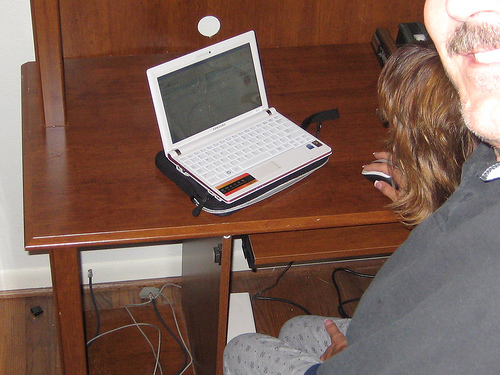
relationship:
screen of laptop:
[172, 42, 261, 136] [145, 29, 333, 205]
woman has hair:
[219, 44, 479, 375] [380, 91, 452, 188]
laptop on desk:
[145, 29, 333, 205] [20, 43, 455, 375]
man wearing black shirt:
[311, 0, 500, 375] [312, 140, 500, 374]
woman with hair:
[219, 44, 479, 375] [372, 32, 479, 229]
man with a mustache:
[311, 0, 500, 375] [434, 18, 498, 55]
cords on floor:
[88, 296, 200, 358] [22, 280, 398, 370]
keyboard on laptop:
[171, 113, 312, 187] [145, 29, 333, 205]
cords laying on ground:
[84, 268, 101, 349] [0, 259, 391, 373]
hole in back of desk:
[185, 11, 227, 53] [10, 26, 442, 294]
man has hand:
[311, 0, 500, 375] [361, 151, 412, 201]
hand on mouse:
[361, 151, 412, 201] [353, 148, 408, 195]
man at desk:
[311, 0, 500, 375] [35, 70, 380, 219]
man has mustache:
[311, 0, 500, 375] [445, 22, 500, 56]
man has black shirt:
[309, 0, 499, 373] [297, 140, 498, 373]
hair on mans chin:
[455, 89, 487, 150] [458, 80, 495, 167]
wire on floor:
[134, 284, 166, 305] [1, 259, 395, 374]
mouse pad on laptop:
[248, 157, 281, 179] [145, 29, 333, 205]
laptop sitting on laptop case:
[145, 29, 333, 205] [155, 105, 345, 217]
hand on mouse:
[359, 148, 406, 201] [361, 149, 407, 199]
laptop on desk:
[127, 40, 337, 220] [12, 54, 396, 368]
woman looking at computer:
[219, 44, 479, 375] [145, 57, 318, 206]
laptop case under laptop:
[152, 148, 333, 216] [123, 34, 382, 221]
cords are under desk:
[257, 258, 368, 309] [7, 0, 479, 374]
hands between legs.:
[316, 319, 350, 355] [284, 317, 345, 365]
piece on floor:
[28, 301, 43, 319] [1, 259, 395, 374]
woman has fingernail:
[360, 43, 467, 224] [362, 149, 382, 191]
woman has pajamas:
[219, 44, 479, 375] [220, 310, 355, 371]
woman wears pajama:
[219, 44, 479, 375] [222, 314, 353, 374]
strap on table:
[301, 105, 344, 127] [18, 1, 427, 370]